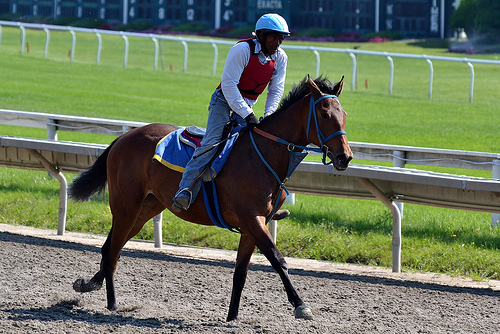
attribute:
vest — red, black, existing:
[217, 36, 277, 103]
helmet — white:
[253, 12, 291, 36]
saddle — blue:
[148, 117, 247, 177]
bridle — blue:
[302, 94, 346, 150]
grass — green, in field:
[0, 23, 499, 279]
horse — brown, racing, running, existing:
[66, 72, 353, 327]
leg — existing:
[88, 181, 151, 312]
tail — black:
[64, 137, 121, 206]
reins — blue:
[249, 121, 324, 156]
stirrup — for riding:
[172, 188, 194, 213]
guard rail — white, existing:
[1, 20, 497, 104]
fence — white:
[0, 108, 499, 277]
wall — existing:
[0, 1, 449, 33]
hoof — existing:
[73, 276, 85, 293]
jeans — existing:
[176, 87, 247, 201]